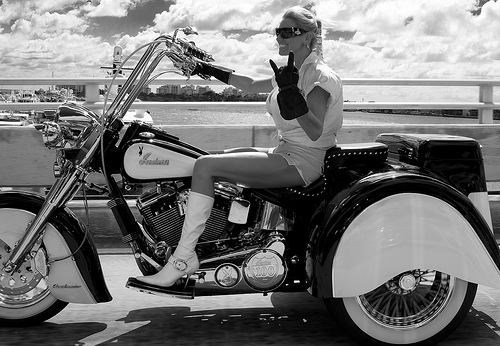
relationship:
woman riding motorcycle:
[138, 3, 344, 291] [1, 25, 498, 345]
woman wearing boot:
[138, 3, 344, 291] [136, 190, 214, 289]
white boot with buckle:
[133, 189, 212, 290] [171, 257, 189, 272]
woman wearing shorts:
[138, 3, 344, 291] [264, 131, 330, 191]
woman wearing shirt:
[138, 3, 344, 291] [260, 47, 348, 150]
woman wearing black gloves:
[138, 3, 344, 291] [263, 50, 309, 121]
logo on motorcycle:
[134, 145, 171, 167] [1, 25, 498, 345]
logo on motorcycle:
[136, 145, 146, 157] [1, 25, 498, 345]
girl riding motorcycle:
[135, 5, 344, 287] [1, 25, 498, 345]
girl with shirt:
[135, 5, 344, 287] [265, 50, 343, 148]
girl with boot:
[135, 5, 344, 287] [136, 190, 214, 289]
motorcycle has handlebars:
[1, 25, 498, 345] [140, 17, 219, 82]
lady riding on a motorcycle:
[123, 18, 342, 293] [1, 25, 498, 345]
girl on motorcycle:
[135, 5, 344, 287] [1, 25, 498, 345]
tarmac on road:
[0, 238, 499, 341] [0, 241, 500, 343]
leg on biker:
[136, 148, 305, 293] [0, 21, 498, 344]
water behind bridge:
[3, 102, 498, 133] [1, 73, 496, 343]